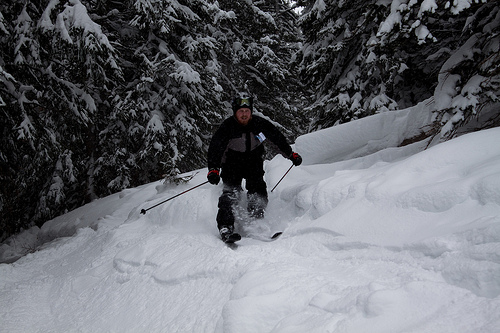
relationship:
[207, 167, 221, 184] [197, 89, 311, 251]
glove on man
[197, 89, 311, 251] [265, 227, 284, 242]
man wearing ski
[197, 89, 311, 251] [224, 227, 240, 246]
man wearing ski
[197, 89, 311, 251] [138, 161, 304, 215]
man holding ski pole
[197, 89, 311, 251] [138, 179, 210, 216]
man holding ski pole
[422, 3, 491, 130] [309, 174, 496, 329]
trees covered with snow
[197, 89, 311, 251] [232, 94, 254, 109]
man wearing hood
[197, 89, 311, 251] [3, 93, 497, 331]
man in snow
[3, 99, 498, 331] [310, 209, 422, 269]
snow on ground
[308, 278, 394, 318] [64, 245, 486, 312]
tracks on snow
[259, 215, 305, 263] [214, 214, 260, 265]
snow ski on snow ski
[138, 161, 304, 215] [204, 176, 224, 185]
ski pole in hand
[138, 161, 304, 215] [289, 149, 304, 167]
ski pole in hand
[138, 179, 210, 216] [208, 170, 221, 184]
ski pole in hand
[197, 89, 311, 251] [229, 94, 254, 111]
man in hat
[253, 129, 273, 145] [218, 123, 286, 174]
ticket attached to jacket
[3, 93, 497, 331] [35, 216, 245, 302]
snow on snow bank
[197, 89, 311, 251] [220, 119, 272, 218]
man wearing snowsuit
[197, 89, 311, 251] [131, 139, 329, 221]
man holding pole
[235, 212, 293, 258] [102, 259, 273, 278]
shadows on ground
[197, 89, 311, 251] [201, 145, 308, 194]
man wearing gloves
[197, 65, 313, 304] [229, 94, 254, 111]
man wearing hat